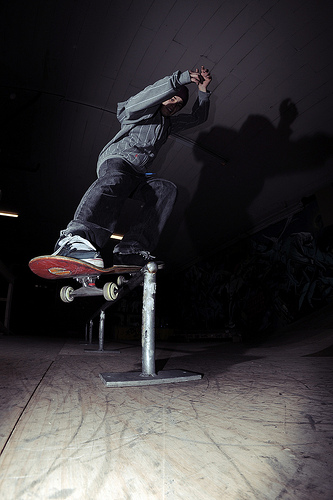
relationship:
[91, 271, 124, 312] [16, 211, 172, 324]
wheel of skateboard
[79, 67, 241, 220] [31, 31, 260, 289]
sweater on man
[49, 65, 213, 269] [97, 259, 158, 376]
boy skateboards on rail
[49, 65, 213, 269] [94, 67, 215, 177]
boy wearing sweater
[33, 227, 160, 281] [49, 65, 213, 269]
shoes on boy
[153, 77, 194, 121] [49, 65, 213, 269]
head of boy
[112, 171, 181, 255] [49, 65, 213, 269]
leg of boy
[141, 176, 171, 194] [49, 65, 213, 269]
thigh of boy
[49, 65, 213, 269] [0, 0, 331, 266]
boy under roof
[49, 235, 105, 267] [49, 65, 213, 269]
foot of a boy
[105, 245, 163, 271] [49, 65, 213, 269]
foot of a boy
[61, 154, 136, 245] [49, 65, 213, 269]
leg on boy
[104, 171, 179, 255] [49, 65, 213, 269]
leg on boy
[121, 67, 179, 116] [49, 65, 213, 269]
arm on boy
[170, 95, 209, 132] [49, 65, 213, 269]
arm on boy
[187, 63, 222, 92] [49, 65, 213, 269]
hand on boy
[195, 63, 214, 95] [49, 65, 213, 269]
hand on boy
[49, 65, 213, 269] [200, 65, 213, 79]
boy has fingers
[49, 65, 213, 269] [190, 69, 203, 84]
boy has fingers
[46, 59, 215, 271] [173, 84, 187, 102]
boy wearing hat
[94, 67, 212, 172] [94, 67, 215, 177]
stripes on sweater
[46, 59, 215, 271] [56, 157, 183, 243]
boy wearing pants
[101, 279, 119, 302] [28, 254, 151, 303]
wheel on board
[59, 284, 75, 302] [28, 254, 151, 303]
wheel on board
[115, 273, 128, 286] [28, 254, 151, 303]
wheel on board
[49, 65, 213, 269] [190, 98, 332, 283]
boy has shadow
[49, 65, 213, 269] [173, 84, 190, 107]
boy wearing hat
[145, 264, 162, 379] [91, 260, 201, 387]
leg on bench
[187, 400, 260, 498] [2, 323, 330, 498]
mark on floor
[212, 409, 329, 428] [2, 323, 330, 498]
mark on floor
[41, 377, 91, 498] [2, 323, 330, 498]
mark on floor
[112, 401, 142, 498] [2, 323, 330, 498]
mark on floor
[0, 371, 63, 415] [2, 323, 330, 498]
mark on floor